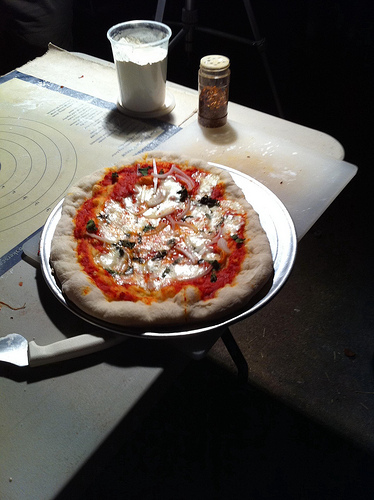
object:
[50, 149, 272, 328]
pizza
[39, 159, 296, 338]
plate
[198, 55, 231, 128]
bottle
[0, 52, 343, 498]
table